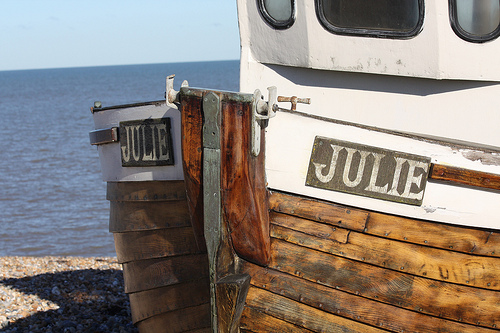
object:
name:
[298, 128, 421, 197]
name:
[113, 117, 174, 171]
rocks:
[52, 286, 61, 294]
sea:
[0, 32, 109, 166]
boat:
[98, 0, 487, 331]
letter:
[388, 154, 405, 198]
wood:
[101, 166, 494, 333]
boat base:
[199, 165, 466, 332]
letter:
[313, 139, 335, 184]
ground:
[51, 257, 83, 310]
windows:
[322, 3, 430, 38]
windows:
[449, 1, 499, 37]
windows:
[257, 2, 309, 37]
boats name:
[110, 117, 180, 172]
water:
[11, 115, 81, 221]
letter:
[118, 125, 133, 165]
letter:
[361, 144, 386, 198]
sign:
[301, 130, 433, 213]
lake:
[0, 55, 247, 260]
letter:
[368, 151, 423, 217]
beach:
[3, 254, 126, 331]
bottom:
[119, 177, 498, 333]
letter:
[130, 124, 141, 162]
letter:
[147, 124, 159, 160]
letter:
[154, 123, 170, 162]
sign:
[118, 116, 177, 168]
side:
[251, 59, 471, 226]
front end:
[163, 1, 498, 330]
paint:
[437, 142, 498, 173]